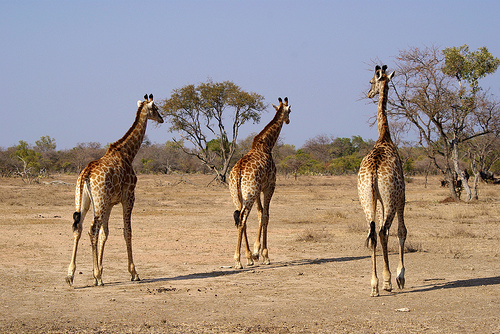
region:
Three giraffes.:
[62, 70, 492, 284]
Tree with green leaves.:
[145, 81, 312, 201]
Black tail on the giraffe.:
[45, 196, 100, 251]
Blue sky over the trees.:
[26, 25, 226, 95]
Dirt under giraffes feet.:
[31, 250, 298, 331]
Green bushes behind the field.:
[300, 138, 417, 173]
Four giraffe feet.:
[65, 246, 140, 291]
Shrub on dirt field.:
[430, 218, 480, 268]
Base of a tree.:
[432, 160, 488, 205]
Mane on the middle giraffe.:
[248, 120, 287, 172]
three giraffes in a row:
[69, 55, 451, 264]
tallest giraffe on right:
[352, 55, 436, 312]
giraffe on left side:
[55, 80, 167, 297]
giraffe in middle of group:
[217, 81, 297, 289]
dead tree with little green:
[407, 40, 492, 212]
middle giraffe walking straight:
[230, 84, 317, 299]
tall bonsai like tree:
[166, 75, 227, 186]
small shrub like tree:
[5, 129, 63, 196]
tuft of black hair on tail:
[225, 207, 243, 233]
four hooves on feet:
[55, 256, 155, 286]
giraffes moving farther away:
[56, 60, 453, 301]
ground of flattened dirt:
[40, 180, 457, 312]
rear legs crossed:
[216, 177, 256, 282]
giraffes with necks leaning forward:
[55, 67, 312, 289]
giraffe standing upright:
[350, 55, 425, 295]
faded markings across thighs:
[345, 161, 407, 221]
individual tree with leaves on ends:
[155, 35, 265, 200]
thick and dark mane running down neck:
[95, 86, 155, 166]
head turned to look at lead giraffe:
[246, 51, 416, 132]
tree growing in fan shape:
[145, 70, 270, 181]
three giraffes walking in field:
[56, 42, 406, 297]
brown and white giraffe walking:
[61, 85, 175, 296]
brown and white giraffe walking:
[223, 88, 299, 281]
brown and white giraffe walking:
[354, 55, 411, 297]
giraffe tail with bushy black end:
[68, 155, 100, 245]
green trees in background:
[4, 40, 499, 204]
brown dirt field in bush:
[8, 175, 498, 323]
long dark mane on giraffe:
[249, 105, 283, 157]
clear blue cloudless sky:
[1, 1, 498, 181]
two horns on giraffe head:
[373, 62, 389, 76]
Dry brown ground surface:
[2, 175, 496, 332]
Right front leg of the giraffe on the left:
[119, 201, 144, 280]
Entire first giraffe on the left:
[64, 91, 164, 288]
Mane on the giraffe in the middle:
[252, 105, 282, 144]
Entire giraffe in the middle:
[228, 96, 294, 271]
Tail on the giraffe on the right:
[364, 168, 378, 253]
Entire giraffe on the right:
[356, 62, 408, 297]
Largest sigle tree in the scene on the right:
[359, 43, 491, 203]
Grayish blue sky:
[3, 0, 493, 139]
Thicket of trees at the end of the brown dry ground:
[3, 146, 496, 175]